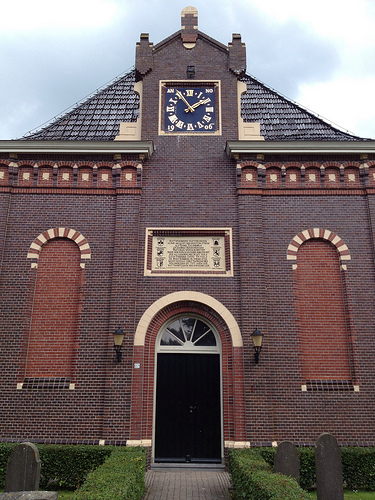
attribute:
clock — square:
[159, 83, 218, 134]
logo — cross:
[178, 5, 198, 29]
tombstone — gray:
[310, 430, 346, 498]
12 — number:
[183, 86, 194, 98]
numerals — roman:
[183, 87, 204, 97]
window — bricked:
[25, 227, 93, 390]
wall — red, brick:
[11, 224, 100, 396]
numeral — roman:
[155, 78, 218, 101]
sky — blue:
[1, 1, 373, 136]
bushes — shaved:
[0, 442, 145, 498]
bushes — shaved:
[226, 441, 374, 497]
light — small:
[109, 316, 132, 366]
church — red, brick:
[7, 11, 369, 445]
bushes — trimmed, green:
[13, 410, 374, 491]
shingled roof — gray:
[17, 26, 368, 140]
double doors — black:
[153, 350, 221, 466]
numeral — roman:
[204, 104, 217, 112]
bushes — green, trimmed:
[220, 436, 272, 498]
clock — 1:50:
[162, 81, 217, 134]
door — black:
[139, 301, 282, 484]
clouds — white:
[314, 19, 364, 90]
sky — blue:
[54, 45, 90, 89]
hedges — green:
[2, 442, 373, 498]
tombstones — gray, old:
[268, 421, 341, 498]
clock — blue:
[158, 84, 216, 130]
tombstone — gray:
[5, 447, 38, 488]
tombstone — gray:
[272, 443, 297, 473]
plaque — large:
[153, 238, 226, 270]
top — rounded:
[25, 225, 89, 266]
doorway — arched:
[150, 306, 227, 468]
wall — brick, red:
[3, 2, 363, 441]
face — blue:
[168, 89, 215, 128]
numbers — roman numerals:
[169, 90, 214, 128]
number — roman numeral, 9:
[163, 104, 178, 110]